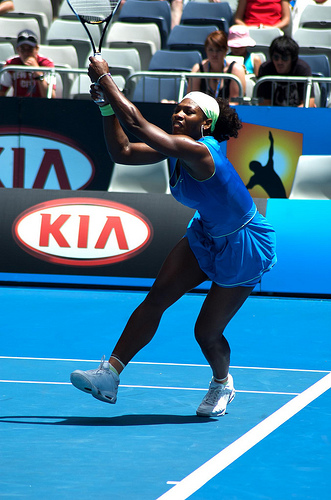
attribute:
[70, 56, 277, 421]
woman — professional, holding, playing, getting ready, ready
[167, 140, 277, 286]
dress — blue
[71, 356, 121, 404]
shoe — white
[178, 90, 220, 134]
headband — white, green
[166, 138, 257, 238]
tank top — blue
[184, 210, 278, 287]
skirt — blue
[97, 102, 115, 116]
wristband — green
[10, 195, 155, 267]
sign — oval, red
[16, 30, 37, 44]
hat — blue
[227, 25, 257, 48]
hat — pink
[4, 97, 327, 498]
tennis court — blue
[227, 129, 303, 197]
sign — yellow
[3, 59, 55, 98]
shirt — red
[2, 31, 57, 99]
spectator — sitting, watching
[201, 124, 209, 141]
earring — large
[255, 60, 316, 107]
shirt — black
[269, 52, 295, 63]
sunglasses — dark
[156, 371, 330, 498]
line — white